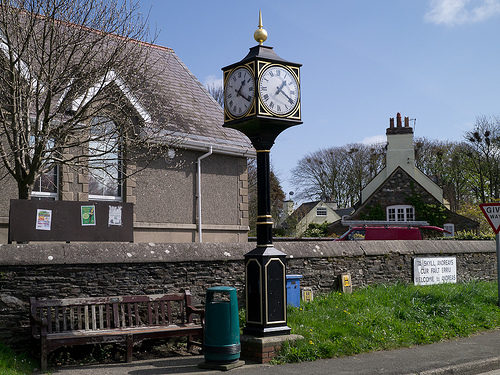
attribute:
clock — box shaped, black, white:
[222, 45, 305, 149]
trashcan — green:
[201, 286, 241, 362]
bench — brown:
[27, 288, 206, 373]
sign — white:
[412, 256, 457, 286]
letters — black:
[421, 266, 452, 274]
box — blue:
[284, 273, 303, 310]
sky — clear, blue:
[1, 1, 500, 214]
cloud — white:
[422, 1, 500, 27]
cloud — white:
[200, 75, 227, 95]